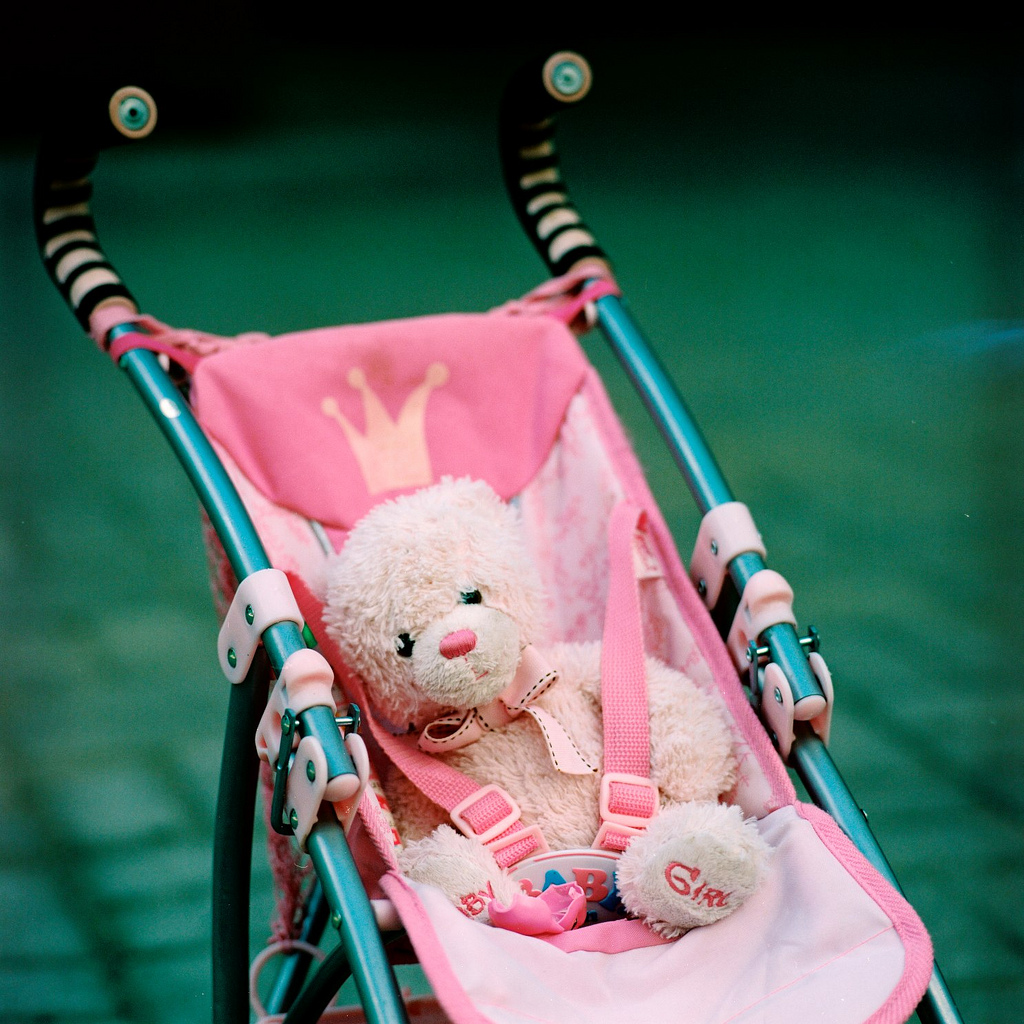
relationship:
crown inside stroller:
[320, 362, 449, 496] [51, 41, 965, 1022]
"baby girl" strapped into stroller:
[321, 473, 762, 942] [51, 41, 965, 1022]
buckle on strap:
[455, 778, 546, 871] [284, 568, 553, 873]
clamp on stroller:
[213, 568, 311, 685] [51, 41, 965, 1022]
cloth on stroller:
[190, 305, 931, 1021] [51, 41, 965, 1022]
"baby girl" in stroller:
[321, 473, 762, 942] [51, 41, 965, 1022]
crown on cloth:
[320, 362, 449, 496] [87, 255, 931, 1022]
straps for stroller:
[593, 510, 650, 856] [51, 41, 965, 1022]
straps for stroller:
[269, 503, 657, 878] [51, 41, 965, 1022]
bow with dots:
[413, 646, 612, 776] [526, 681, 537, 694]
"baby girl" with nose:
[321, 473, 762, 942] [433, 621, 481, 660]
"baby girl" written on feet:
[394, 796, 766, 937] [400, 804, 764, 934]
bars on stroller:
[117, 338, 355, 803] [51, 41, 965, 1022]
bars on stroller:
[590, 296, 817, 700] [51, 41, 965, 1022]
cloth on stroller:
[87, 255, 931, 1022] [51, 41, 965, 1022]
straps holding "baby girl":
[301, 506, 654, 889] [321, 473, 762, 942]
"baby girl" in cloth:
[321, 473, 762, 942] [87, 255, 931, 1022]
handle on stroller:
[489, 33, 619, 275] [51, 41, 965, 1022]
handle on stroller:
[22, 61, 163, 312] [51, 41, 965, 1022]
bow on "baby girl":
[417, 643, 597, 775] [321, 473, 762, 942]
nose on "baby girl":
[433, 618, 483, 660] [321, 473, 762, 942]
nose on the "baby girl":
[440, 630, 476, 660] [321, 473, 762, 942]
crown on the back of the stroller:
[314, 355, 462, 494] [51, 41, 965, 1022]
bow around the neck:
[417, 643, 597, 775] [415, 647, 571, 738]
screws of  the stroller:
[283, 732, 370, 854] [51, 41, 965, 1022]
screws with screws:
[283, 732, 370, 854] [219, 595, 313, 824]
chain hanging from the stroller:
[243, 754, 336, 1005] [51, 41, 965, 1022]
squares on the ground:
[35, 748, 193, 857] [22, 35, 993, 990]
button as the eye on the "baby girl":
[456, 580, 496, 613] [321, 473, 762, 942]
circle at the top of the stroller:
[539, 50, 596, 102] [51, 41, 965, 1022]